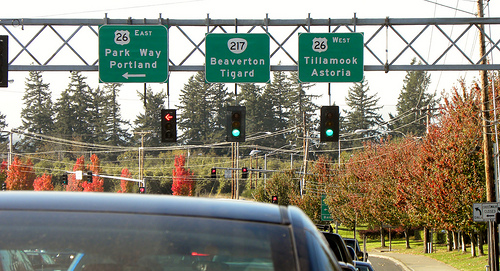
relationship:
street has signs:
[67, 194, 410, 269] [103, 26, 370, 83]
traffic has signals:
[0, 177, 372, 260] [156, 108, 351, 149]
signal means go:
[215, 96, 246, 148] [232, 127, 243, 137]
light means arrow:
[161, 110, 177, 143] [163, 113, 175, 121]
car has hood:
[0, 186, 312, 267] [12, 189, 297, 232]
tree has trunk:
[398, 134, 436, 243] [418, 226, 432, 251]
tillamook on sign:
[300, 53, 359, 68] [296, 31, 364, 81]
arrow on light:
[162, 110, 175, 119] [161, 110, 177, 143]